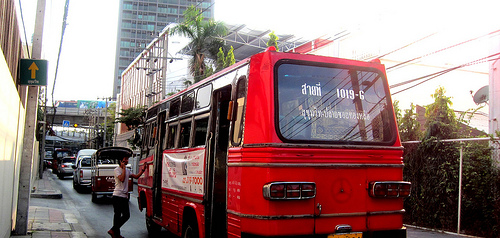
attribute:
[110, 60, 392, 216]
bus — red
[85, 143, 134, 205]
vehicle — red, white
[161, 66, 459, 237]
bus — red, city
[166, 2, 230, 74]
tree — palm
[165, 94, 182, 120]
window — tinted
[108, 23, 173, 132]
facade — orange, white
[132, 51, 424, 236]
window — tinted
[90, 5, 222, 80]
apartment building — tall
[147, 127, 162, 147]
window — tinted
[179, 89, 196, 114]
window — tinted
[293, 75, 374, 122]
writing — Thai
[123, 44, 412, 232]
bus — red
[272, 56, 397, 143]
window — tinted, rear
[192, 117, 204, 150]
window — tinted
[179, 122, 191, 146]
window — tinted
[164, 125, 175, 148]
window — tinted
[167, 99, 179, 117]
window — tinted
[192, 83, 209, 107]
window — tinted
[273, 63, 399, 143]
window — tinted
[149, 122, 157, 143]
window — tinted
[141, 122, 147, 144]
window — tinted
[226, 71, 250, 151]
window — tinted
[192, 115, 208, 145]
window — tinted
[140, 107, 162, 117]
window — tinted